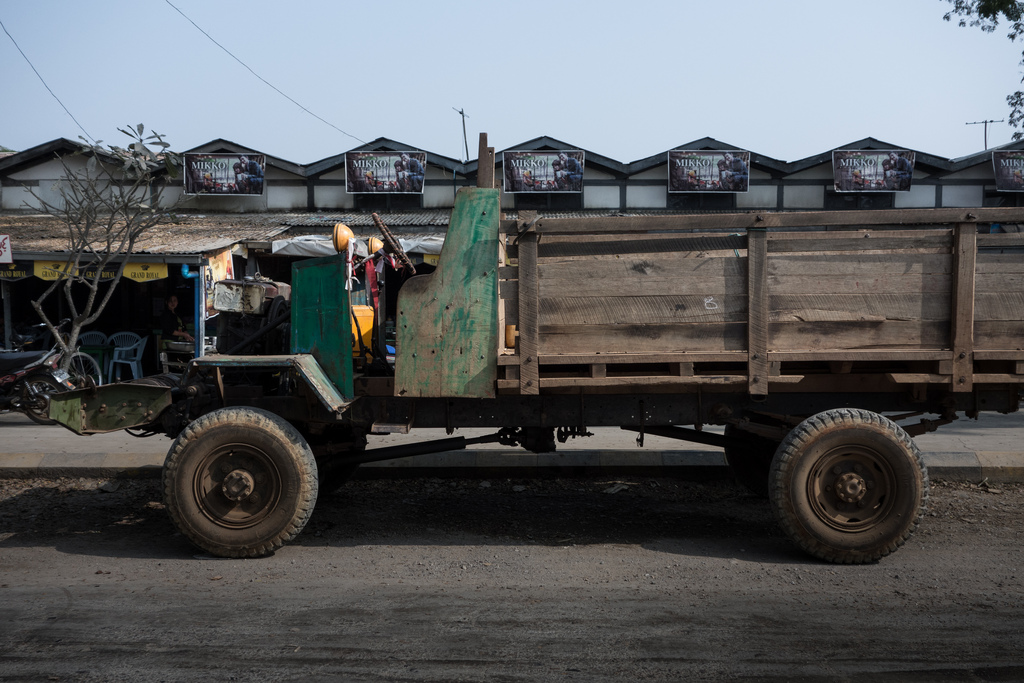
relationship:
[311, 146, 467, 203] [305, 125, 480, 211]
wall on side of a building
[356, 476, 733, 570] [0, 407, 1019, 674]
shadow on road